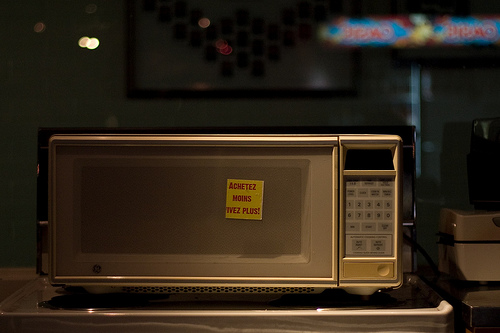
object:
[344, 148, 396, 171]
screen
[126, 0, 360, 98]
picture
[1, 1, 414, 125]
wall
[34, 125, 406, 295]
zebra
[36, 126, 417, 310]
microwave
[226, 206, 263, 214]
word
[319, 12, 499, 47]
sign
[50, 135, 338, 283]
door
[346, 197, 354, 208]
buttons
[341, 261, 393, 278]
button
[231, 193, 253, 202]
red lettering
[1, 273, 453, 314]
countertop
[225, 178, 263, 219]
print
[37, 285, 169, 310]
underside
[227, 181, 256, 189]
lettering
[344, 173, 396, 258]
control panel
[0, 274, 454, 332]
counter